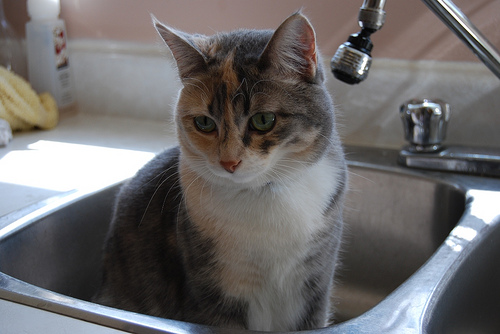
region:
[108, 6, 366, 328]
Cat sits in a sink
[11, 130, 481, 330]
Sink of kitchen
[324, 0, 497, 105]
Faucet of sink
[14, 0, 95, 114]
Empty bottle on counter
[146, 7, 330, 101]
Ears of cat has white hair inside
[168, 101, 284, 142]
Eyes of cat are big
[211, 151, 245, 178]
Nose of cat is pink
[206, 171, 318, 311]
Chest of cat is white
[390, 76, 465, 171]
Knob of sink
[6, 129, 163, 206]
Sunshine on counter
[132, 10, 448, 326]
cat sitting in kitchen sink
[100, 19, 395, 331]
black, tan and white cat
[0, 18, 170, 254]
bright sunny day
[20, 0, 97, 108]
hand soap on the counter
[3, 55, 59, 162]
yellow towel on the counter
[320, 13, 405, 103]
adjustable sink faucet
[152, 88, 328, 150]
cat with green eyes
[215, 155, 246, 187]
cat with pink nose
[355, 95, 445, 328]
sink with no water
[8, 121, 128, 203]
sun shining on counter top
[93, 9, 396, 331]
a cat in a sink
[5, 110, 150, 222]
shiny surface of the top of a sink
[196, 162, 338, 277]
white part of a cat's neck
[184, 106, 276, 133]
grey eyes of a cat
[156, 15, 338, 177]
brown and grey head of a cat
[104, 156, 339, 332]
white and grey body of a cat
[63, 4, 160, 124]
brown and white wall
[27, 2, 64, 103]
a small white bottle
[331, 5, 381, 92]
the top part of a tap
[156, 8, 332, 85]
the ears of a cat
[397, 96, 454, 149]
chrome colored hot water knob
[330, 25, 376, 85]
chrome and black sink sprayer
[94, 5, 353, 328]
calico cat in a sink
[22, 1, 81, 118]
Bath and Body brand soap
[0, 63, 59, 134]
yellow wash cloth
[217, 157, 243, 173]
pink cat nose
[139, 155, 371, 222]
white cat whiskers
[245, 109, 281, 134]
left green cat eye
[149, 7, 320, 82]
furry cat ears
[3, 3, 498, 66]
pink wall behind sink in kitchen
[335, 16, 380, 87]
Water spout attached to the faucet.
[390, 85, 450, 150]
Round faucet handle in the center of the sink.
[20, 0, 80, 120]
Bottle of soap on the left.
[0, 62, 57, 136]
The yellow rag next to the bottle of soap.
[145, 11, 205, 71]
The cat's left ear.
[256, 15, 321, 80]
The cat's right ear.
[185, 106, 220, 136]
The cat's left eye.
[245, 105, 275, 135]
The cat's right eye.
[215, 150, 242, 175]
The cat's little pink nose.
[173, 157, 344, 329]
The cat's white patch of fur in the center of its body.